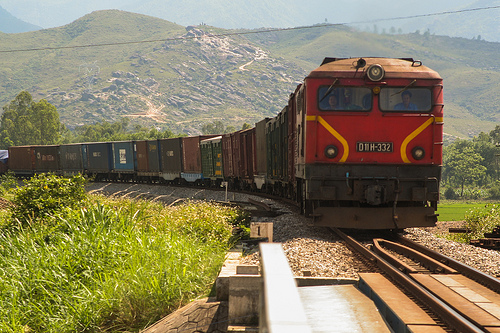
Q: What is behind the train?
A: Mountains.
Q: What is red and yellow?
A: The locomotive.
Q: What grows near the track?
A: Grass.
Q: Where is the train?
A: On the tracks.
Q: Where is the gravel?
A: Under the train.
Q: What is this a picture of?
A: Trai.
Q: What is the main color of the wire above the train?
A: Black.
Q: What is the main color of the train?
A: Red.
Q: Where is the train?
A: Train tracks.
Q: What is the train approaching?
A: Trestle.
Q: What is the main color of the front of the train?
A: Red.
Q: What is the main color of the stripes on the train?
A: Yellow.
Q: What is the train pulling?
A: Freight cars.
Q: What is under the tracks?
A: Gravel.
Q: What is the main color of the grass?
A: Green.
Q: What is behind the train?
A: A mountain.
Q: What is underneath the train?
A: Tracks.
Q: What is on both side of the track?
A: Rocks.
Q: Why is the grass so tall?
A: It hasn't been cut.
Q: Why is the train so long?
A: It is pulling multiple cars.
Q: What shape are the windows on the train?
A: Rectangular.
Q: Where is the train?
A: Tracks.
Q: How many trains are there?
A: One.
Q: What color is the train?
A: Red.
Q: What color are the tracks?
A: Brown.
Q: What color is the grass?
A: Green.